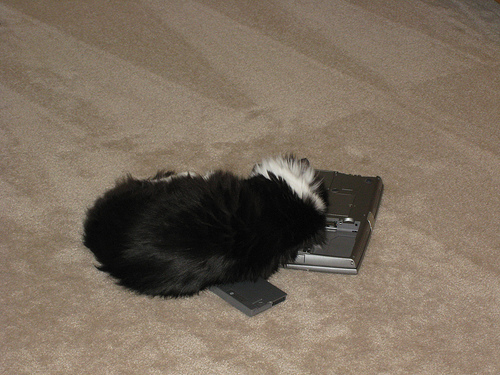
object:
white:
[289, 177, 299, 187]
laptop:
[279, 170, 382, 275]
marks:
[0, 21, 135, 154]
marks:
[0, 0, 288, 130]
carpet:
[0, 0, 499, 374]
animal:
[78, 151, 333, 302]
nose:
[254, 160, 260, 167]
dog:
[77, 150, 331, 303]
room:
[0, 1, 498, 373]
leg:
[147, 171, 180, 184]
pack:
[205, 276, 288, 316]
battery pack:
[275, 170, 383, 275]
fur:
[124, 192, 247, 253]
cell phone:
[208, 274, 292, 317]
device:
[280, 169, 383, 275]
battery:
[207, 281, 289, 318]